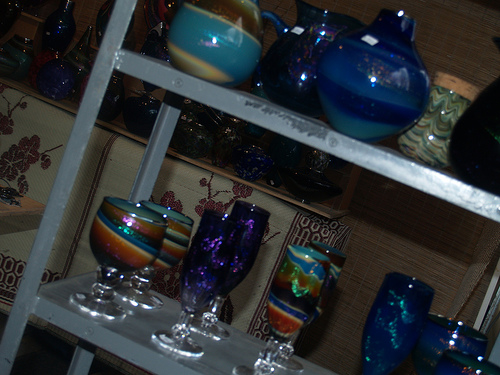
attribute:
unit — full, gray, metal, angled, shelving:
[1, 1, 498, 375]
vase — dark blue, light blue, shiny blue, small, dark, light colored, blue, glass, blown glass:
[309, 5, 432, 147]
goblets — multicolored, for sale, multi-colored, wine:
[231, 241, 334, 372]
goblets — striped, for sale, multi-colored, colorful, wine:
[260, 237, 347, 367]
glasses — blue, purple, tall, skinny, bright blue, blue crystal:
[147, 205, 249, 366]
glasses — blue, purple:
[194, 196, 272, 348]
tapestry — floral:
[1, 88, 352, 372]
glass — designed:
[397, 84, 475, 174]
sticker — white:
[358, 32, 378, 50]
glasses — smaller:
[60, 194, 167, 329]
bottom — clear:
[147, 325, 208, 362]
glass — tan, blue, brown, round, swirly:
[165, 0, 272, 91]